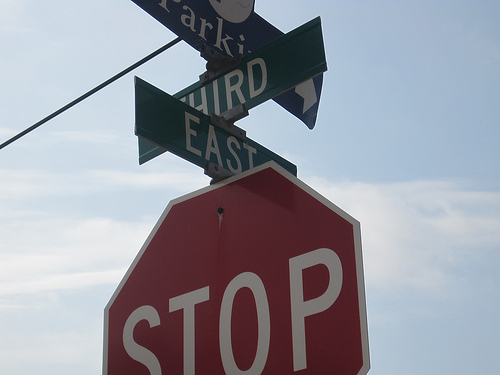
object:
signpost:
[101, 159, 370, 374]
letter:
[119, 303, 165, 374]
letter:
[166, 284, 210, 374]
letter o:
[213, 270, 274, 375]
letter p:
[287, 246, 344, 372]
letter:
[182, 109, 206, 158]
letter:
[222, 136, 245, 175]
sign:
[132, 74, 297, 179]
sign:
[135, 14, 328, 165]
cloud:
[0, 0, 499, 374]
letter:
[202, 122, 223, 167]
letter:
[239, 138, 260, 170]